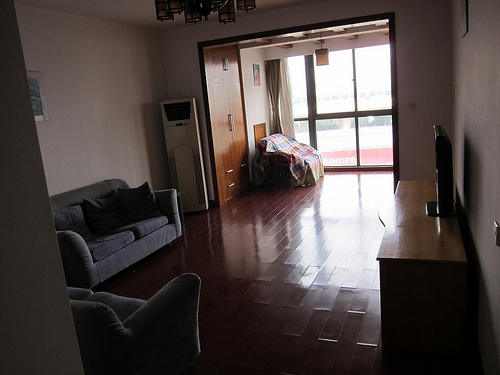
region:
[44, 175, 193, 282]
a couch in a living room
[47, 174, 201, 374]
the couches look gray in the living room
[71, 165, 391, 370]
the floor is wooden and brown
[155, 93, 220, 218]
a room heater is in the corner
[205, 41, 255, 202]
a built in cabinet with drawers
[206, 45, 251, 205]
the cabinet in the living room is wooden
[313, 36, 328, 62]
a light fixture is hanging from the ceiling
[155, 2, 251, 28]
a black light fixture is hanging from the ceiling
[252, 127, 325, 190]
a chair is next to the windows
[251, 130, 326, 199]
the chair is covered with a blanket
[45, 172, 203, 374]
matching set of couches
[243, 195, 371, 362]
dark wood flooring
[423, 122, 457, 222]
black flat screen television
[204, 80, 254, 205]
built in storage closet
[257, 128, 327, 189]
furniture covered with a blanket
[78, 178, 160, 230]
two couch accent pillows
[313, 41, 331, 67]
cylindrical hanging light fixture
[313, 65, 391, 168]
large glass windows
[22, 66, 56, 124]
artwork hanging on the wall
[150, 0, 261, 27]
small hanging ligh fixture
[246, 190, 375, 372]
brown wood flooring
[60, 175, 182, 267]
two pillows on a gray couch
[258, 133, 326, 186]
furniture covered with a multicolored blanket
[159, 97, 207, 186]
tall white appliance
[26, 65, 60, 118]
art hanging on the wall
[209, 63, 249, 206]
brown wooden closet door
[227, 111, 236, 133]
silver handles on a wooden closet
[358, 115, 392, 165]
window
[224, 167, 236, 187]
two handles on wooden structure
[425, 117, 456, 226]
black television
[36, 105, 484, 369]
Office waiting room foyer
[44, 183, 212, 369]
Dark gray sofa and loveseat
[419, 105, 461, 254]
Flat screen television off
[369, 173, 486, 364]
High gloss wood credenza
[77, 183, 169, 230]
Two dark toss pillows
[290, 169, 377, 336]
Tile floor recently buffed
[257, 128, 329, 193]
Plaid blanket covers chair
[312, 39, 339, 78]
Lamp shade over ceiling light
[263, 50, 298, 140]
Draw curtains provide privacy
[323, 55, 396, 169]
Plate glass window hazy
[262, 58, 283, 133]
tied back curtains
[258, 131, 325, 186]
chair with multi colored throw blanket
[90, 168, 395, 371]
wood-like tile flooring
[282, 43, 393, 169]
large window with metal divisions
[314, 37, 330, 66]
lamp hanging from ceiling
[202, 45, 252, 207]
floor-to-ceiling storage closet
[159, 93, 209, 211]
old fashioned wall furnace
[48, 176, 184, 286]
blue couch with a pillow on it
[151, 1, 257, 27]
multi-light ceiling lamp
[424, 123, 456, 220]
flat screened television